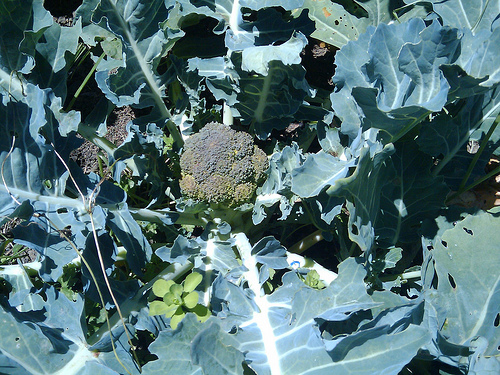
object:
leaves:
[106, 42, 288, 108]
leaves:
[0, 0, 498, 374]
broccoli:
[180, 123, 268, 206]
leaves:
[310, 7, 484, 351]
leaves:
[332, 150, 385, 270]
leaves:
[353, 17, 453, 136]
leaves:
[216, 229, 424, 374]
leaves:
[93, 4, 180, 104]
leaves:
[234, 40, 307, 135]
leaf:
[328, 16, 457, 138]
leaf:
[287, 135, 395, 201]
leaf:
[205, 234, 427, 375]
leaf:
[413, 206, 497, 369]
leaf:
[0, 172, 109, 249]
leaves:
[0, 280, 117, 373]